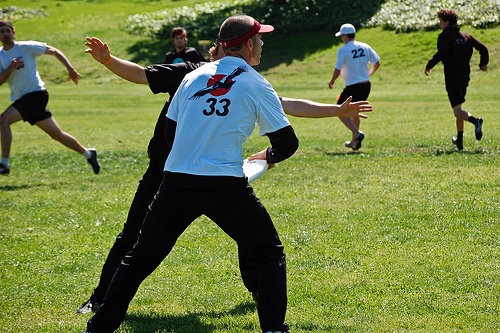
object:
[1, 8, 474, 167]
competitors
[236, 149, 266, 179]
frisbee contest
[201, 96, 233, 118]
33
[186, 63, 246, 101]
logo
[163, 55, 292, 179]
shirt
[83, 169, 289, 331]
pants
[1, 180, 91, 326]
grass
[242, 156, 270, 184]
frisbee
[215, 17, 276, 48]
visor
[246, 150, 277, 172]
right hand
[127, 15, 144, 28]
flowers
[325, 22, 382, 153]
player 22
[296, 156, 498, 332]
field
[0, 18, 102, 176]
person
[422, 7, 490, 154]
person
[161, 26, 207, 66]
person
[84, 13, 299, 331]
person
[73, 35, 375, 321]
person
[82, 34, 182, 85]
arm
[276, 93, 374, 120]
arms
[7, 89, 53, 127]
shorts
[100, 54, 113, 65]
bracelet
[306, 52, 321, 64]
22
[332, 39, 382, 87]
shirt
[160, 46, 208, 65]
shirt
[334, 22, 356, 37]
ballcap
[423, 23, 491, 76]
clothes